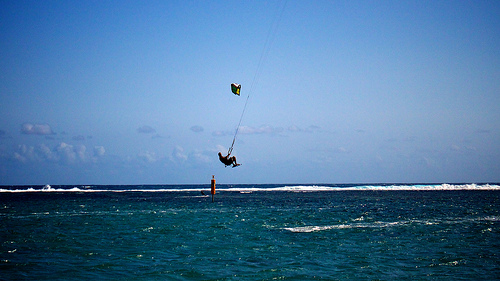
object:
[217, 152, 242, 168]
man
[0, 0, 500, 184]
sky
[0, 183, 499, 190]
wave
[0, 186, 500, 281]
ocean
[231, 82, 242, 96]
kite